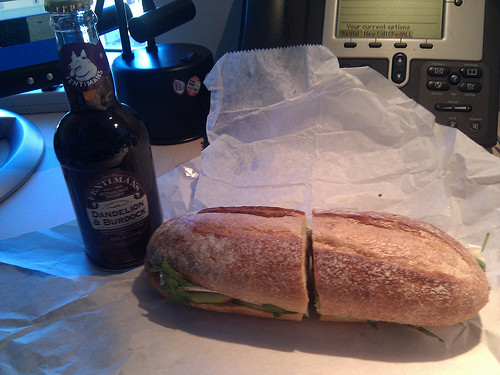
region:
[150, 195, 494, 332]
Sandwich is long and brown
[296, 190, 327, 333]
Cleft in middle of food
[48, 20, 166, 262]
Brown beer in bottle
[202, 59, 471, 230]
Sandwich wrapper is white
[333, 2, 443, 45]
Screen of phone in background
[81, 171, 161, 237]
Label on bottle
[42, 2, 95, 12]
Beer cap of bottle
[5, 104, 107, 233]
Top of desk is brown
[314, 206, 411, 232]
Edge of sandwich has ridge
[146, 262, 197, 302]
Lettuce in food is sticking out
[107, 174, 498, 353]
a sandwich on a table.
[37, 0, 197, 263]
a bottle on a table.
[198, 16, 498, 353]
a sandwich wrapper.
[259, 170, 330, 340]
a cut line on a sandwich.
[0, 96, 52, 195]
a white bowl on a floor.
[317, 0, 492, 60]
a TV on a wall.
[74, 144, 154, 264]
a label on a bottle.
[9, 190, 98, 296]
a section of a counter.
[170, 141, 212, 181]
light reflecting on a counter.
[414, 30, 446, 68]
a knob on a TV.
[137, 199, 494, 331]
Sandwich is made of bread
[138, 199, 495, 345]
Sanwich has lettuce in it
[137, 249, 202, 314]
lettuce is green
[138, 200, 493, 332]
Bread is light brown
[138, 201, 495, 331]
Bread is crusty and toasted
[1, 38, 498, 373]
White paper is under the sandwich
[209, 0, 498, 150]
Phone is black and silver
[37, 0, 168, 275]
Glass bottle next to sandwich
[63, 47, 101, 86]
Dog on bottle logo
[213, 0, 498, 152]
Buttons on phone are black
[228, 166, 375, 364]
a sandwich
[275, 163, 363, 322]
a sandwich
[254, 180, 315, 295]
a sandwich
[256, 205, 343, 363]
a sandwich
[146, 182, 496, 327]
Sandwich on paper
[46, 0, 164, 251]
Brown beer bottle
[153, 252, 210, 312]
Lettuce on food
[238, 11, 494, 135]
Phone in background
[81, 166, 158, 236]
Label is brown and white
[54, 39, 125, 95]
Wolf head on bottle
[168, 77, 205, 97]
Scan tags in background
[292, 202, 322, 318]
Cleft of sandwich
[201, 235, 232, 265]
Small bits of flour on bread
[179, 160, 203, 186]
Gleaming piece of paper